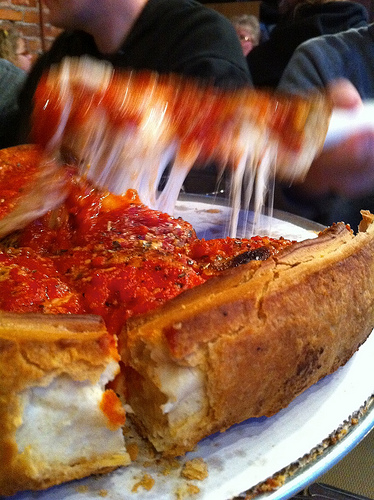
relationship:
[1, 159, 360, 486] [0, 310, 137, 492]
bread has bread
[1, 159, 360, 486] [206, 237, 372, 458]
bread has crust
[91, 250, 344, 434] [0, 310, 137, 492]
bread has bread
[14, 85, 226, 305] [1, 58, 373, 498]
red sauce on pizza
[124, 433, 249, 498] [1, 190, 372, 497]
trimming on plate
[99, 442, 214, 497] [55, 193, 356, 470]
crumbs are on plate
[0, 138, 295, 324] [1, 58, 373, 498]
red sauce on pizza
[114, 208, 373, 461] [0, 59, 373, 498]
bread on pizza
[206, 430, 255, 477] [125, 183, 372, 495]
stains are on plate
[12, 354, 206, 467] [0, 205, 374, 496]
cheese in crust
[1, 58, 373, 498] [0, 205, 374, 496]
pizza has crust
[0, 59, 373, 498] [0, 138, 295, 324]
pizza has red sauce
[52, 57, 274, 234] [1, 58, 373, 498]
cheese on pizza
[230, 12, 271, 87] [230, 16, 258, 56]
person has head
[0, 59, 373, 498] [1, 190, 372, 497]
pizza on plate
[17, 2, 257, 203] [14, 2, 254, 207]
man wearing shirt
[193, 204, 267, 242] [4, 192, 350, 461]
shadow under pizza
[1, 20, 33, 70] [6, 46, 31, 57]
woman wearing glasses